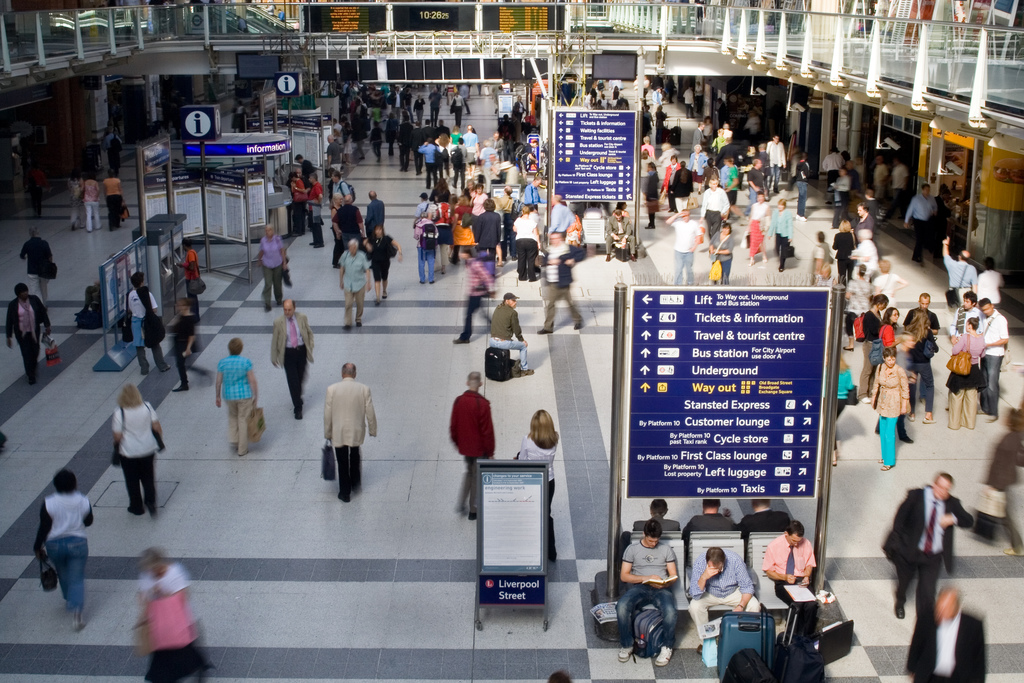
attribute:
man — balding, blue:
[932, 230, 974, 297]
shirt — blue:
[692, 566, 753, 605]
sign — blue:
[604, 281, 834, 504]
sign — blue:
[541, 104, 648, 211]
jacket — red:
[442, 387, 505, 468]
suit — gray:
[317, 370, 387, 504]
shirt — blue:
[209, 341, 261, 413]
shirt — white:
[103, 398, 170, 463]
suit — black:
[894, 594, 994, 679]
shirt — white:
[663, 207, 703, 259]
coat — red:
[436, 384, 514, 475]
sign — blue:
[613, 270, 843, 508]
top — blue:
[211, 348, 261, 409]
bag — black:
[474, 335, 522, 388]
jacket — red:
[446, 378, 514, 467]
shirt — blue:
[204, 348, 271, 413]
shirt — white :
[44, 489, 96, 539]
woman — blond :
[113, 382, 168, 508]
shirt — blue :
[221, 354, 260, 396]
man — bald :
[323, 358, 376, 497]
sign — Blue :
[619, 287, 825, 497]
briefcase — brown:
[319, 444, 335, 484]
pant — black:
[331, 440, 368, 501]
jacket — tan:
[319, 381, 382, 448]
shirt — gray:
[628, 539, 678, 579]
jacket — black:
[900, 604, 991, 680]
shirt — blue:
[221, 349, 252, 402]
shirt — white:
[671, 213, 698, 253]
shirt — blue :
[213, 356, 257, 400]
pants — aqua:
[868, 419, 905, 471]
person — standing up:
[516, 406, 564, 573]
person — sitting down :
[605, 503, 701, 670]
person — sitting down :
[676, 544, 750, 637]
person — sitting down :
[758, 510, 832, 644]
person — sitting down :
[631, 496, 679, 533]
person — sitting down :
[680, 496, 735, 525]